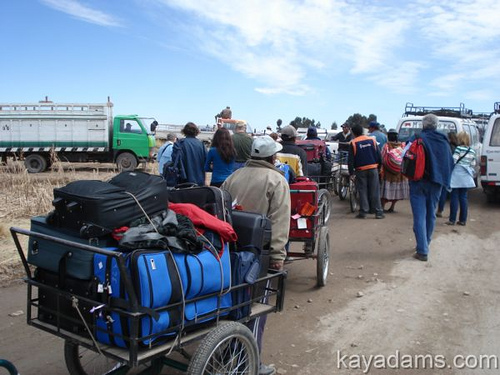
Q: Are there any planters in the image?
A: No, there are no planters.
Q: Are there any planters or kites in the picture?
A: No, there are no planters or kites.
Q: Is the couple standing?
A: Yes, the couple is standing.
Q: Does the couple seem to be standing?
A: Yes, the couple is standing.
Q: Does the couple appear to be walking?
A: No, the couple is standing.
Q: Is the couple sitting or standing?
A: The couple is standing.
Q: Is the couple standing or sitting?
A: The couple is standing.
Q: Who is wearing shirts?
A: The couple is wearing shirts.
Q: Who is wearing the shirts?
A: The couple is wearing shirts.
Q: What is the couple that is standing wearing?
A: The couple is wearing shirts.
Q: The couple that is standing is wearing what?
A: The couple is wearing shirts.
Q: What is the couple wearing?
A: The couple is wearing shirts.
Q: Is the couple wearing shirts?
A: Yes, the couple is wearing shirts.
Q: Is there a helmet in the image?
A: No, there are no helmets.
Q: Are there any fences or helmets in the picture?
A: No, there are no helmets or fences.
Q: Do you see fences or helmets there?
A: No, there are no helmets or fences.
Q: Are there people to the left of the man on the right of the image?
A: Yes, there is a person to the left of the man.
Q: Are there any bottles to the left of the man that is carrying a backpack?
A: No, there is a person to the left of the man.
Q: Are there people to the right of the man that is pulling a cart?
A: Yes, there is a person to the right of the man.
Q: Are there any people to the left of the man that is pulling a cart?
A: No, the person is to the right of the man.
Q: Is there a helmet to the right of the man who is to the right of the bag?
A: No, there is a person to the right of the man.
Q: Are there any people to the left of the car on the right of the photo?
A: Yes, there is a person to the left of the car.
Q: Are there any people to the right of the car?
A: No, the person is to the left of the car.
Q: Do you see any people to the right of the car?
A: No, the person is to the left of the car.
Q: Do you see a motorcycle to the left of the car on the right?
A: No, there is a person to the left of the car.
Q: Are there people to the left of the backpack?
A: Yes, there is a person to the left of the backpack.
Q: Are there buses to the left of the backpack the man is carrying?
A: No, there is a person to the left of the backpack.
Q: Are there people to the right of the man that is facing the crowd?
A: Yes, there is a person to the right of the man.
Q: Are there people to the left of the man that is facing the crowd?
A: No, the person is to the right of the man.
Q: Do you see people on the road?
A: Yes, there is a person on the road.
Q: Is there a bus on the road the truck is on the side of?
A: No, there is a person on the road.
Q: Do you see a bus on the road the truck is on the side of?
A: No, there is a person on the road.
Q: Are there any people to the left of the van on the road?
A: Yes, there is a person to the left of the van.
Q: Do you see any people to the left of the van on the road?
A: Yes, there is a person to the left of the van.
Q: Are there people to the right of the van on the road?
A: No, the person is to the left of the van.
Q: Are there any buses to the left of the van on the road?
A: No, there is a person to the left of the van.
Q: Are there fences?
A: No, there are no fences.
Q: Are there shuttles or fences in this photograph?
A: No, there are no fences or shuttles.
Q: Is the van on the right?
A: Yes, the van is on the right of the image.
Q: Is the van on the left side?
A: No, the van is on the right of the image.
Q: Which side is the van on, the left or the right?
A: The van is on the right of the image.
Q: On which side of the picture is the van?
A: The van is on the right of the image.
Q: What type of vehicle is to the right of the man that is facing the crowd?
A: The vehicle is a van.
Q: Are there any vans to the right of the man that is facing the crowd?
A: Yes, there is a van to the right of the man.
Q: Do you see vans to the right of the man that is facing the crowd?
A: Yes, there is a van to the right of the man.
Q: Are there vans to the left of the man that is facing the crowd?
A: No, the van is to the right of the man.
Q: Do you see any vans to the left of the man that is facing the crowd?
A: No, the van is to the right of the man.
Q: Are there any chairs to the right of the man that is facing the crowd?
A: No, there is a van to the right of the man.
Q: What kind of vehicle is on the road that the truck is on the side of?
A: The vehicle is a van.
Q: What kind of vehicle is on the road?
A: The vehicle is a van.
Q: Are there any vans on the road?
A: Yes, there is a van on the road.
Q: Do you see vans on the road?
A: Yes, there is a van on the road.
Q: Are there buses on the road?
A: No, there is a van on the road.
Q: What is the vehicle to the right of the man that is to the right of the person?
A: The vehicle is a van.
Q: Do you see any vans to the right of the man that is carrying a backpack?
A: Yes, there is a van to the right of the man.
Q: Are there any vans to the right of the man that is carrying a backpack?
A: Yes, there is a van to the right of the man.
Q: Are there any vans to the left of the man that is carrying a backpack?
A: No, the van is to the right of the man.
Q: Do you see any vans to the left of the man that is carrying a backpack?
A: No, the van is to the right of the man.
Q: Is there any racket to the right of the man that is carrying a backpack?
A: No, there is a van to the right of the man.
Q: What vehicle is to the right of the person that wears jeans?
A: The vehicle is a van.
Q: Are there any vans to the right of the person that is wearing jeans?
A: Yes, there is a van to the right of the person.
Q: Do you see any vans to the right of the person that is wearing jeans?
A: Yes, there is a van to the right of the person.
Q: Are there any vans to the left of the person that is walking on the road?
A: No, the van is to the right of the person.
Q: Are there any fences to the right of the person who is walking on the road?
A: No, there is a van to the right of the person.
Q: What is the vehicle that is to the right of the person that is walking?
A: The vehicle is a van.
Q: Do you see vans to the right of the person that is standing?
A: Yes, there is a van to the right of the person.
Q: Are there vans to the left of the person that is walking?
A: No, the van is to the right of the person.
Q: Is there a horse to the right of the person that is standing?
A: No, there is a van to the right of the person.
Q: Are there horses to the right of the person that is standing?
A: No, there is a van to the right of the person.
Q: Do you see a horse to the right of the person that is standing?
A: No, there is a van to the right of the person.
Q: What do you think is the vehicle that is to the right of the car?
A: The vehicle is a van.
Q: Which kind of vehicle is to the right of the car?
A: The vehicle is a van.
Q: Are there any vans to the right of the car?
A: Yes, there is a van to the right of the car.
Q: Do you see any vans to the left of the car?
A: No, the van is to the right of the car.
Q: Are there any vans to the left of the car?
A: No, the van is to the right of the car.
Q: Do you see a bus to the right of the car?
A: No, there is a van to the right of the car.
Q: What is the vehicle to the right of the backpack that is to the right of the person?
A: The vehicle is a van.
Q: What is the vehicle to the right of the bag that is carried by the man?
A: The vehicle is a van.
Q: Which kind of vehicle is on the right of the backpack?
A: The vehicle is a van.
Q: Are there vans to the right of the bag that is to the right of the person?
A: Yes, there is a van to the right of the backpack.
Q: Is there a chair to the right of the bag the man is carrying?
A: No, there is a van to the right of the backpack.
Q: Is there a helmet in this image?
A: No, there are no helmets.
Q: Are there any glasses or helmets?
A: No, there are no helmets or glasses.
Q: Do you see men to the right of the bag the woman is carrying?
A: Yes, there is a man to the right of the bag.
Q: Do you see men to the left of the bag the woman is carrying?
A: No, the man is to the right of the bag.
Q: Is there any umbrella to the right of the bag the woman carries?
A: No, there is a man to the right of the bag.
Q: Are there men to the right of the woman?
A: Yes, there is a man to the right of the woman.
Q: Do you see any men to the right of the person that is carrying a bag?
A: Yes, there is a man to the right of the woman.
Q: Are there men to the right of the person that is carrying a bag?
A: Yes, there is a man to the right of the woman.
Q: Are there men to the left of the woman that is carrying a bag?
A: No, the man is to the right of the woman.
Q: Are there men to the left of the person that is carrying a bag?
A: No, the man is to the right of the woman.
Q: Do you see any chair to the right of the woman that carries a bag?
A: No, there is a man to the right of the woman.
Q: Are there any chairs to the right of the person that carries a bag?
A: No, there is a man to the right of the woman.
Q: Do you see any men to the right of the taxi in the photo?
A: Yes, there is a man to the right of the taxi.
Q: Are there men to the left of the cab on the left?
A: No, the man is to the right of the cab.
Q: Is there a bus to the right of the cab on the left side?
A: No, there is a man to the right of the taxi.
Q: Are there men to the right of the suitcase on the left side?
A: Yes, there is a man to the right of the suitcase.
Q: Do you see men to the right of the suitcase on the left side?
A: Yes, there is a man to the right of the suitcase.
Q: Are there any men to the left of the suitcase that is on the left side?
A: No, the man is to the right of the suitcase.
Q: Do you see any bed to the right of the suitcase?
A: No, there is a man to the right of the suitcase.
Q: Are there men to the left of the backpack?
A: Yes, there is a man to the left of the backpack.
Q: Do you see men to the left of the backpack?
A: Yes, there is a man to the left of the backpack.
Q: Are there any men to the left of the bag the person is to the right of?
A: Yes, there is a man to the left of the backpack.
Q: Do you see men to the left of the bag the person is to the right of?
A: Yes, there is a man to the left of the backpack.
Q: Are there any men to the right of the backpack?
A: No, the man is to the left of the backpack.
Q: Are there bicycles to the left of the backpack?
A: No, there is a man to the left of the backpack.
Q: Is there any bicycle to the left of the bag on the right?
A: No, there is a man to the left of the backpack.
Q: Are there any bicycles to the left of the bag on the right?
A: No, there is a man to the left of the backpack.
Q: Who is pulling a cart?
A: The man is pulling a cart.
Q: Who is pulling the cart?
A: The man is pulling a cart.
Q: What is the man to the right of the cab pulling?
A: The man is pulling a cart.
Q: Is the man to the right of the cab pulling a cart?
A: Yes, the man is pulling a cart.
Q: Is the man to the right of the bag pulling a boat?
A: No, the man is pulling a cart.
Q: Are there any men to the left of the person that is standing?
A: Yes, there is a man to the left of the person.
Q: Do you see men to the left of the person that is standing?
A: Yes, there is a man to the left of the person.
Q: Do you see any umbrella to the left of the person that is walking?
A: No, there is a man to the left of the person.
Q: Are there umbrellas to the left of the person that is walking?
A: No, there is a man to the left of the person.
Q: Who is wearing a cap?
A: The man is wearing a cap.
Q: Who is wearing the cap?
A: The man is wearing a cap.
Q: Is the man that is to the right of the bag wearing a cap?
A: Yes, the man is wearing a cap.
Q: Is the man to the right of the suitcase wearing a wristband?
A: No, the man is wearing a cap.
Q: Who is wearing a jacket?
A: The man is wearing a jacket.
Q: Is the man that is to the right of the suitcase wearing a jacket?
A: Yes, the man is wearing a jacket.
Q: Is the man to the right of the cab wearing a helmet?
A: No, the man is wearing a jacket.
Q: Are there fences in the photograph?
A: No, there are no fences.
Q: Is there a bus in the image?
A: No, there are no buses.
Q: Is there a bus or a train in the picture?
A: No, there are no buses or trains.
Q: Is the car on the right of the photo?
A: Yes, the car is on the right of the image.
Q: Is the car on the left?
A: No, the car is on the right of the image.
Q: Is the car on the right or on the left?
A: The car is on the right of the image.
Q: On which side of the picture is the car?
A: The car is on the right of the image.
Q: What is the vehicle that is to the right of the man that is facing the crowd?
A: The vehicle is a car.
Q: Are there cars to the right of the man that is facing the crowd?
A: Yes, there is a car to the right of the man.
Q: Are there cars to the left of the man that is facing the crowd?
A: No, the car is to the right of the man.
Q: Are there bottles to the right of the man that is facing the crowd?
A: No, there is a car to the right of the man.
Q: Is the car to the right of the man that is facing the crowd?
A: Yes, the car is to the right of the man.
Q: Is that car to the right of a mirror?
A: No, the car is to the right of the man.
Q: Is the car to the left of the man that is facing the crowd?
A: No, the car is to the right of the man.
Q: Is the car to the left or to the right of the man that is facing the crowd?
A: The car is to the right of the man.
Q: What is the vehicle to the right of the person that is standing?
A: The vehicle is a car.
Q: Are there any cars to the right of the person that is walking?
A: Yes, there is a car to the right of the person.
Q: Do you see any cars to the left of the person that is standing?
A: No, the car is to the right of the person.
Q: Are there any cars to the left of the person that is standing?
A: No, the car is to the right of the person.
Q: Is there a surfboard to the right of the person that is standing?
A: No, there is a car to the right of the person.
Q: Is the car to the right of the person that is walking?
A: Yes, the car is to the right of the person.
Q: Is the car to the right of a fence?
A: No, the car is to the right of the person.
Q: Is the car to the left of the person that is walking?
A: No, the car is to the right of the person.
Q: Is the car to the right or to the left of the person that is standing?
A: The car is to the right of the person.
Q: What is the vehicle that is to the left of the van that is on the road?
A: The vehicle is a car.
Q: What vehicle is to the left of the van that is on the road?
A: The vehicle is a car.